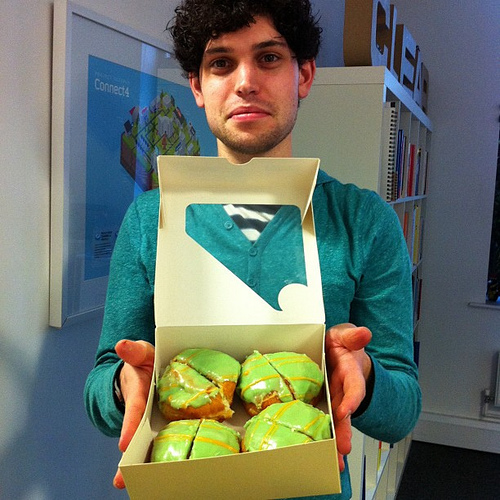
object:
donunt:
[148, 415, 239, 463]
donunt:
[159, 345, 243, 420]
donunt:
[240, 351, 326, 413]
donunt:
[239, 397, 332, 457]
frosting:
[163, 362, 216, 403]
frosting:
[245, 371, 276, 396]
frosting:
[154, 437, 202, 459]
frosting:
[246, 420, 298, 454]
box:
[116, 152, 343, 499]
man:
[85, 3, 421, 500]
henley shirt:
[81, 173, 420, 500]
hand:
[113, 332, 157, 488]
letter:
[343, 1, 394, 67]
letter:
[386, 4, 401, 82]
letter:
[393, 22, 417, 100]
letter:
[413, 51, 424, 104]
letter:
[420, 62, 429, 114]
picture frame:
[50, 0, 182, 330]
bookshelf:
[265, 65, 432, 499]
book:
[393, 129, 405, 197]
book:
[406, 139, 415, 196]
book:
[384, 102, 397, 198]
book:
[406, 211, 414, 264]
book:
[411, 205, 424, 263]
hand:
[324, 318, 372, 471]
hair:
[164, 0, 325, 80]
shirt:
[221, 204, 282, 244]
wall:
[0, 2, 175, 500]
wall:
[308, 1, 499, 451]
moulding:
[411, 411, 500, 452]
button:
[247, 276, 256, 286]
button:
[248, 245, 258, 256]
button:
[223, 220, 234, 230]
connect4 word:
[92, 77, 131, 99]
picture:
[78, 16, 220, 315]